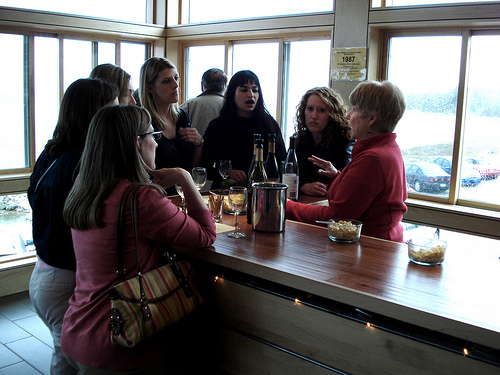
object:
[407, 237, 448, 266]
bowl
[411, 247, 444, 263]
nuts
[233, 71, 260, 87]
bangs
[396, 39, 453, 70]
sky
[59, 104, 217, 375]
she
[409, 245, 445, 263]
food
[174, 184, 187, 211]
glass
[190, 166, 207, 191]
glass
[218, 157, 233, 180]
glass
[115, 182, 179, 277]
straps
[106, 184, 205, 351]
purse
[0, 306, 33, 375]
ground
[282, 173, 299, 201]
label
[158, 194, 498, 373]
bar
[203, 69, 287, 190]
woman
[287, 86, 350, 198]
woman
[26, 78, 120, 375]
woman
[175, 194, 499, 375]
table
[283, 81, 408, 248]
woman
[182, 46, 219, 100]
window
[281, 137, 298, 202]
bottles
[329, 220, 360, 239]
food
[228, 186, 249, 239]
wine glass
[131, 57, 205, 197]
woman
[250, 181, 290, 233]
bucket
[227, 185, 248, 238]
glass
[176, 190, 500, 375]
counter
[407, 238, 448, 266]
glass bowl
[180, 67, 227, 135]
woman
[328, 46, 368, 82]
sign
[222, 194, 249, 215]
bowl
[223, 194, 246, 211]
food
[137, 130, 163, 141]
glasses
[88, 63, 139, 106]
woman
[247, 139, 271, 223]
bottle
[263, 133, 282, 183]
bottle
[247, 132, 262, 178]
bottle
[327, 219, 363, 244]
bowl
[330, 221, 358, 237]
nuts